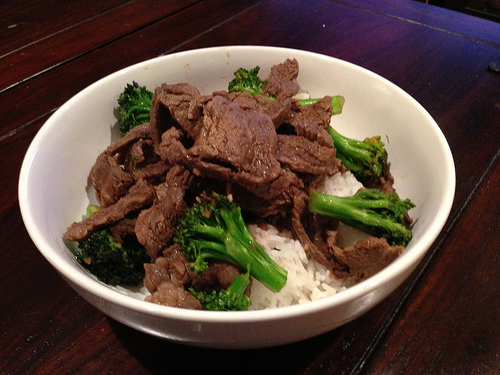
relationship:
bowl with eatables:
[16, 45, 457, 350] [61, 57, 413, 310]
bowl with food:
[53, 41, 474, 316] [118, 86, 349, 256]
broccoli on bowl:
[181, 195, 286, 292] [16, 45, 457, 350]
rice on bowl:
[247, 168, 362, 310] [16, 45, 457, 350]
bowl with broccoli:
[16, 45, 457, 350] [174, 191, 287, 294]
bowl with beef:
[16, 45, 457, 350] [60, 174, 164, 242]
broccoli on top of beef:
[308, 186, 415, 243] [291, 194, 411, 289]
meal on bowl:
[68, 50, 419, 317] [16, 45, 457, 350]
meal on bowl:
[78, 71, 398, 301] [16, 45, 457, 350]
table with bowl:
[0, 2, 497, 371] [16, 45, 457, 350]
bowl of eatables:
[16, 45, 457, 350] [61, 57, 413, 310]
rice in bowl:
[246, 223, 349, 312] [16, 45, 457, 350]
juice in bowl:
[185, 48, 232, 82] [16, 45, 457, 350]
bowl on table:
[16, 45, 457, 350] [0, 2, 497, 371]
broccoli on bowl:
[113, 79, 155, 131] [16, 45, 457, 350]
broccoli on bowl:
[228, 64, 275, 101] [16, 45, 457, 350]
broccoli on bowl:
[323, 128, 387, 186] [16, 45, 457, 350]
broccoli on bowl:
[308, 186, 415, 243] [16, 45, 457, 350]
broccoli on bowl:
[174, 191, 287, 294] [16, 45, 457, 350]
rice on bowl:
[246, 223, 349, 312] [16, 45, 457, 350]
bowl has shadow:
[16, 45, 457, 350] [126, 343, 357, 374]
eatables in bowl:
[64, 48, 407, 310] [16, 45, 457, 350]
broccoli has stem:
[182, 181, 296, 307] [221, 223, 284, 293]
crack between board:
[352, 156, 497, 371] [385, 303, 497, 360]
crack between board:
[2, 2, 246, 99] [43, 71, 71, 101]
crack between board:
[0, 285, 91, 366] [85, 18, 115, 47]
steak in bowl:
[65, 57, 412, 308] [16, 45, 457, 350]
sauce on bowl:
[181, 54, 261, 81] [49, 26, 420, 213]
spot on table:
[323, 20, 326, 30] [0, 2, 497, 371]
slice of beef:
[165, 121, 252, 199] [164, 95, 324, 236]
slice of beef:
[171, 103, 249, 223] [88, 146, 218, 266]